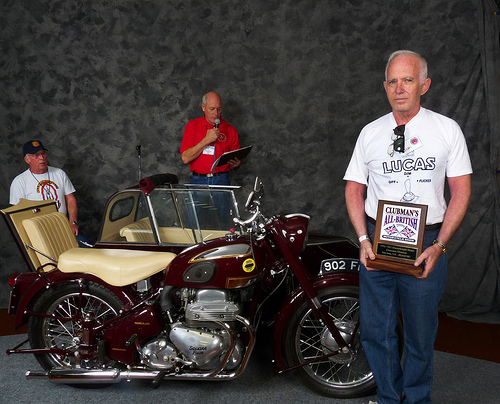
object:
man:
[344, 49, 474, 402]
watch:
[357, 234, 371, 242]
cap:
[24, 139, 44, 155]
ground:
[375, 167, 381, 174]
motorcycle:
[0, 176, 405, 398]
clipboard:
[209, 143, 254, 172]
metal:
[364, 198, 460, 279]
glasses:
[389, 123, 407, 156]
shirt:
[180, 117, 242, 172]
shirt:
[8, 165, 76, 215]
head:
[382, 49, 432, 115]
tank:
[170, 235, 274, 292]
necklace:
[29, 169, 52, 200]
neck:
[28, 169, 52, 174]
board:
[363, 199, 428, 278]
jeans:
[359, 218, 450, 402]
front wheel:
[284, 286, 403, 398]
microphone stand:
[136, 143, 143, 181]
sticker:
[242, 258, 255, 272]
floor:
[253, 379, 283, 396]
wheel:
[15, 272, 144, 388]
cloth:
[0, 0, 499, 329]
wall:
[0, 1, 497, 356]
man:
[9, 140, 77, 238]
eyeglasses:
[29, 151, 46, 157]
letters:
[382, 157, 436, 174]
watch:
[431, 238, 451, 252]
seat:
[0, 197, 175, 286]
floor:
[57, 372, 114, 404]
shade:
[249, 337, 281, 379]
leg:
[400, 267, 441, 400]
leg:
[360, 261, 404, 401]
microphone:
[215, 118, 220, 128]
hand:
[206, 127, 220, 142]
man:
[178, 89, 241, 226]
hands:
[359, 239, 381, 271]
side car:
[97, 173, 360, 252]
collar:
[389, 108, 422, 127]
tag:
[203, 145, 216, 156]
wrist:
[430, 240, 450, 255]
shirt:
[342, 107, 473, 228]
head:
[201, 91, 223, 123]